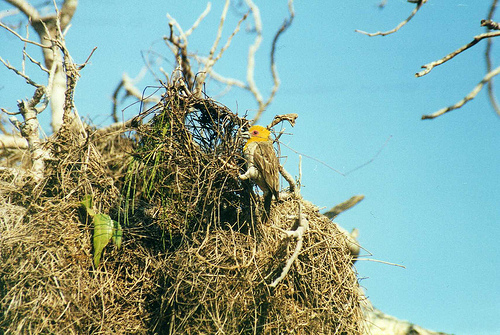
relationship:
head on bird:
[234, 121, 279, 150] [232, 116, 284, 198]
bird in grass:
[235, 125, 279, 224] [66, 125, 379, 327]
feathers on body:
[254, 143, 278, 199] [244, 142, 279, 199]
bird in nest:
[235, 125, 279, 224] [92, 127, 231, 252]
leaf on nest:
[84, 194, 123, 265] [0, 24, 405, 333]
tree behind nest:
[0, 0, 498, 331] [132, 78, 233, 220]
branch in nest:
[277, 168, 307, 288] [0, 24, 405, 333]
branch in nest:
[164, 7, 211, 102] [0, 24, 405, 333]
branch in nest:
[228, 4, 268, 117] [0, 24, 405, 333]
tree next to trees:
[3, 4, 97, 226] [111, 2, 498, 334]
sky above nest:
[0, 1, 499, 331] [3, 80, 361, 332]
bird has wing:
[235, 125, 279, 224] [254, 142, 281, 202]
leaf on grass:
[79, 194, 122, 269] [80, 158, 270, 299]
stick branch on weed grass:
[269, 200, 306, 289] [1, 60, 368, 333]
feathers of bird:
[252, 142, 279, 201] [234, 121, 281, 202]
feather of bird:
[260, 141, 275, 156] [234, 121, 281, 202]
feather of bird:
[268, 157, 279, 169] [234, 121, 281, 202]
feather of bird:
[271, 180, 281, 195] [234, 121, 281, 202]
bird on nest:
[235, 125, 279, 224] [66, 93, 370, 331]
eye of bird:
[251, 130, 260, 136] [238, 121, 278, 204]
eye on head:
[248, 130, 261, 141] [245, 124, 266, 141]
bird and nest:
[236, 127, 282, 205] [147, 99, 310, 273]